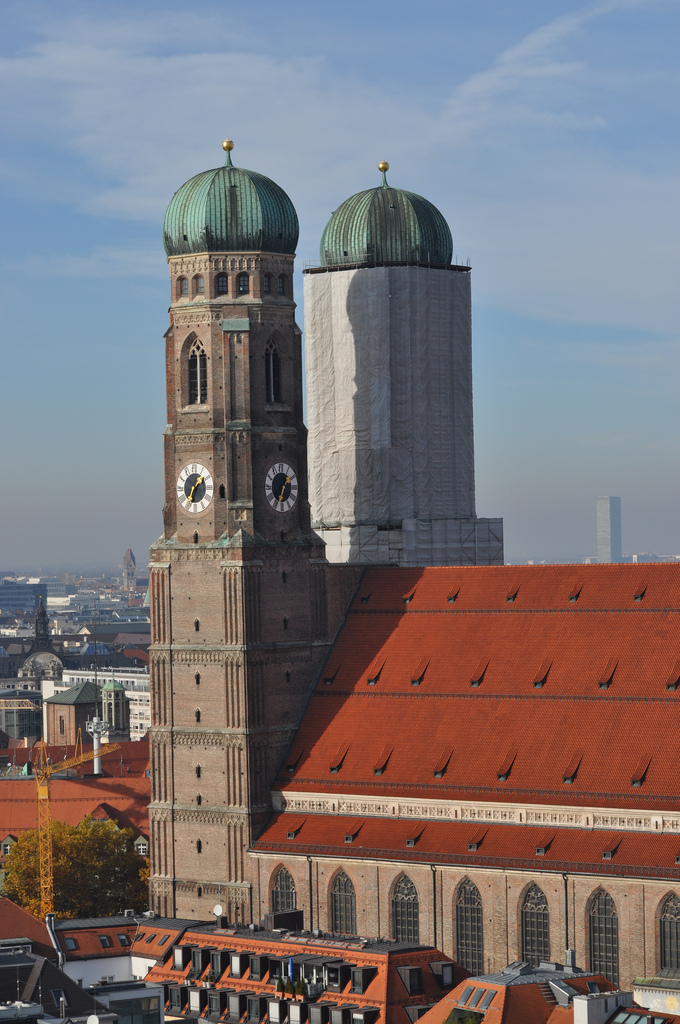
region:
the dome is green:
[298, 151, 474, 287]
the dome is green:
[147, 126, 308, 271]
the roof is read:
[246, 545, 679, 897]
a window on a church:
[263, 856, 304, 923]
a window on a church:
[322, 863, 359, 935]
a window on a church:
[380, 865, 429, 947]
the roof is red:
[0, 770, 158, 850]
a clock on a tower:
[165, 456, 223, 523]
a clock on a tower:
[253, 455, 308, 520]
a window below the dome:
[176, 322, 216, 423]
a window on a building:
[181, 335, 210, 399]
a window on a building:
[259, 866, 306, 932]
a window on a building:
[329, 866, 367, 927]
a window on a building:
[445, 890, 483, 979]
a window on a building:
[517, 889, 551, 978]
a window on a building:
[586, 894, 617, 995]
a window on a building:
[653, 897, 678, 986]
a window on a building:
[192, 761, 205, 775]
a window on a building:
[182, 795, 212, 808]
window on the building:
[162, 940, 189, 971]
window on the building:
[192, 945, 204, 973]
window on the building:
[208, 947, 228, 978]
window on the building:
[349, 963, 366, 1001]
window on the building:
[328, 964, 342, 992]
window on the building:
[297, 965, 317, 986]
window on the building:
[267, 956, 286, 990]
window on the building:
[283, 1003, 301, 1020]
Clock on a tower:
[166, 452, 224, 525]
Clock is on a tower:
[166, 451, 231, 523]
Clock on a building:
[167, 455, 229, 523]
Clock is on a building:
[167, 450, 232, 524]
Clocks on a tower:
[163, 449, 315, 525]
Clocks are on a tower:
[170, 448, 312, 523]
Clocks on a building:
[161, 455, 307, 521]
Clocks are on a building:
[167, 449, 314, 526]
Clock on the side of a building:
[170, 450, 221, 518]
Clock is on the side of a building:
[169, 452, 225, 514]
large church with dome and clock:
[123, 126, 677, 923]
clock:
[159, 452, 226, 531]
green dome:
[137, 157, 294, 285]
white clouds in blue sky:
[44, 165, 85, 217]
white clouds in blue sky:
[492, 177, 525, 211]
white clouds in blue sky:
[553, 167, 614, 229]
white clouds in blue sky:
[516, 459, 555, 502]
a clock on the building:
[178, 461, 213, 518]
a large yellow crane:
[28, 738, 130, 916]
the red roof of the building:
[271, 563, 679, 866]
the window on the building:
[452, 884, 484, 969]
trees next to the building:
[10, 818, 141, 915]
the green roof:
[166, 169, 297, 256]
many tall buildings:
[9, 569, 169, 1017]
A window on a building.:
[328, 866, 356, 935]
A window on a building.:
[386, 872, 418, 941]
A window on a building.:
[453, 876, 487, 972]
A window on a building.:
[519, 880, 553, 966]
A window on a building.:
[586, 885, 619, 987]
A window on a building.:
[653, 889, 673, 979]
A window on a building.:
[601, 850, 610, 862]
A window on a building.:
[469, 843, 478, 849]